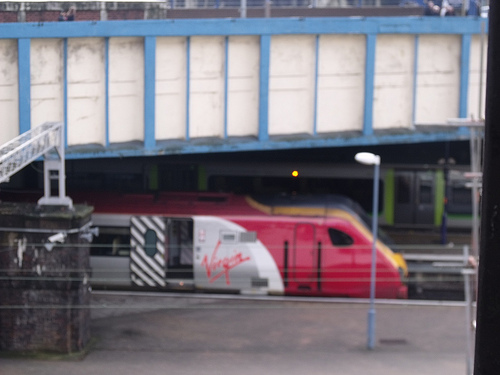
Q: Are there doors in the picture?
A: Yes, there is a door.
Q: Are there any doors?
A: Yes, there is a door.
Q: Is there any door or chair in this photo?
A: Yes, there is a door.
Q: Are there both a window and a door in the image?
A: Yes, there are both a door and a window.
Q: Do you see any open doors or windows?
A: Yes, there is an open door.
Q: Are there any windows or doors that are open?
A: Yes, the door is open.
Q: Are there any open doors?
A: Yes, there is an open door.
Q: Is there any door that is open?
A: Yes, there is a door that is open.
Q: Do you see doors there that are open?
A: Yes, there is a door that is open.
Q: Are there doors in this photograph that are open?
A: Yes, there is a door that is open.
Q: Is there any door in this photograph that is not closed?
A: Yes, there is a open door.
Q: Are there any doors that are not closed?
A: Yes, there is a open door.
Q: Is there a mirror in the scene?
A: No, there are no mirrors.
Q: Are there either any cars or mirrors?
A: No, there are no mirrors or cars.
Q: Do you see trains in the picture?
A: Yes, there is a train.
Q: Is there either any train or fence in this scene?
A: Yes, there is a train.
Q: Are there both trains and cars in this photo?
A: No, there is a train but no cars.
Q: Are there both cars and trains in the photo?
A: No, there is a train but no cars.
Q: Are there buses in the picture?
A: No, there are no buses.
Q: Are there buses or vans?
A: No, there are no buses or vans.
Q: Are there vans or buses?
A: No, there are no buses or vans.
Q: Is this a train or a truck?
A: This is a train.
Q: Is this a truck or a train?
A: This is a train.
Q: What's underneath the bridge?
A: The train is underneath the bridge.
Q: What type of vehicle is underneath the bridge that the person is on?
A: The vehicle is a train.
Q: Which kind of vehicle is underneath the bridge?
A: The vehicle is a train.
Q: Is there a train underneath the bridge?
A: Yes, there is a train underneath the bridge.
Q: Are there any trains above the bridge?
A: No, the train is underneath the bridge.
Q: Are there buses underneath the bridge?
A: No, there is a train underneath the bridge.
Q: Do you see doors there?
A: Yes, there are doors.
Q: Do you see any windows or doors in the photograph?
A: Yes, there are doors.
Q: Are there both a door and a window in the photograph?
A: Yes, there are both a door and a window.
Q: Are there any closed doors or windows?
A: Yes, there are closed doors.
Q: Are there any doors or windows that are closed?
A: Yes, the doors are closed.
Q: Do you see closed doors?
A: Yes, there are closed doors.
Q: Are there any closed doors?
A: Yes, there are closed doors.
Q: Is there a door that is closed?
A: Yes, there are doors that are closed.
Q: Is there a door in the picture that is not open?
A: Yes, there are closed doors.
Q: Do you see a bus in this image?
A: No, there are no buses.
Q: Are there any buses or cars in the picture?
A: No, there are no buses or cars.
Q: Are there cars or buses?
A: No, there are no buses or cars.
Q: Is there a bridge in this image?
A: Yes, there is a bridge.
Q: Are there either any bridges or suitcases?
A: Yes, there is a bridge.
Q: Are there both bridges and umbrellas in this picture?
A: No, there is a bridge but no umbrellas.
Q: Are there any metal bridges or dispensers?
A: Yes, there is a metal bridge.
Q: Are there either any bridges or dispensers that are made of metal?
A: Yes, the bridge is made of metal.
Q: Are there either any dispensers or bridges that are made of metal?
A: Yes, the bridge is made of metal.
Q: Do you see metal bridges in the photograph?
A: Yes, there is a metal bridge.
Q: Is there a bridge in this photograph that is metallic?
A: Yes, there is a bridge that is metallic.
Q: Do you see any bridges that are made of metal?
A: Yes, there is a bridge that is made of metal.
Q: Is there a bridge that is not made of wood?
A: Yes, there is a bridge that is made of metal.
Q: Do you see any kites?
A: No, there are no kites.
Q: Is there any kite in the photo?
A: No, there are no kites.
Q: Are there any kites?
A: No, there are no kites.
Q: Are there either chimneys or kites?
A: No, there are no kites or chimneys.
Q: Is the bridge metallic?
A: Yes, the bridge is metallic.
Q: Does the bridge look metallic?
A: Yes, the bridge is metallic.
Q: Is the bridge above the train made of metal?
A: Yes, the bridge is made of metal.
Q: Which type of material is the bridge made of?
A: The bridge is made of metal.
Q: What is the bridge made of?
A: The bridge is made of metal.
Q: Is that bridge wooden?
A: No, the bridge is metallic.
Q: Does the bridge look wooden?
A: No, the bridge is metallic.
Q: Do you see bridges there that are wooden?
A: No, there is a bridge but it is metallic.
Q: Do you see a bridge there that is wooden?
A: No, there is a bridge but it is metallic.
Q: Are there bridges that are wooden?
A: No, there is a bridge but it is metallic.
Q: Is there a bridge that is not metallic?
A: No, there is a bridge but it is metallic.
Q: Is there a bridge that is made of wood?
A: No, there is a bridge but it is made of metal.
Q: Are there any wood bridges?
A: No, there is a bridge but it is made of metal.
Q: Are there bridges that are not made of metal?
A: No, there is a bridge but it is made of metal.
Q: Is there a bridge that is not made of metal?
A: No, there is a bridge but it is made of metal.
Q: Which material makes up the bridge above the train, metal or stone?
A: The bridge is made of metal.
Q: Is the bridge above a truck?
A: No, the bridge is above a train.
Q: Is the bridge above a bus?
A: No, the bridge is above the train.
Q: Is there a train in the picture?
A: Yes, there is a train.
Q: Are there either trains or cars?
A: Yes, there is a train.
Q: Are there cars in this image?
A: No, there are no cars.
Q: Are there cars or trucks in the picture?
A: No, there are no cars or trucks.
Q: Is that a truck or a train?
A: That is a train.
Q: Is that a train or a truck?
A: That is a train.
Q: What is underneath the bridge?
A: The train is underneath the bridge.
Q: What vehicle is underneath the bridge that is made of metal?
A: The vehicle is a train.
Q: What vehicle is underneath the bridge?
A: The vehicle is a train.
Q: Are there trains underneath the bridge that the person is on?
A: Yes, there is a train underneath the bridge.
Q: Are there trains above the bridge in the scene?
A: No, the train is underneath the bridge.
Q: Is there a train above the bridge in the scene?
A: No, the train is underneath the bridge.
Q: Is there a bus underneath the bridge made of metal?
A: No, there is a train underneath the bridge.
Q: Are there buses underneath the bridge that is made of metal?
A: No, there is a train underneath the bridge.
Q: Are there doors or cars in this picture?
A: Yes, there is a door.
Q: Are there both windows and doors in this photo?
A: Yes, there are both a door and a window.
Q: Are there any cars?
A: No, there are no cars.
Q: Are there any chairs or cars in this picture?
A: No, there are no cars or chairs.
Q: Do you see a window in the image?
A: Yes, there is a window.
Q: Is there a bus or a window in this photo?
A: Yes, there is a window.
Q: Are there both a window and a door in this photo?
A: Yes, there are both a window and a door.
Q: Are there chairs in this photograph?
A: No, there are no chairs.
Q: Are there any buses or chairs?
A: No, there are no chairs or buses.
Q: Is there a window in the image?
A: Yes, there is a window.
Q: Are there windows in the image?
A: Yes, there is a window.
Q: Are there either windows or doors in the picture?
A: Yes, there is a window.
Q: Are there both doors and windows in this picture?
A: Yes, there are both a window and a door.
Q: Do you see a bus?
A: No, there are no buses.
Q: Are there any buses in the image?
A: No, there are no buses.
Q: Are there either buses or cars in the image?
A: No, there are no buses or cars.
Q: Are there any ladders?
A: No, there are no ladders.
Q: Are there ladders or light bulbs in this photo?
A: No, there are no ladders or light bulbs.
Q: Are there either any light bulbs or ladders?
A: No, there are no ladders or light bulbs.